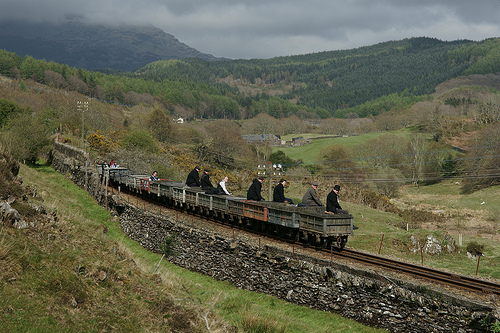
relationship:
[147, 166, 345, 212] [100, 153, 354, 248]
people on train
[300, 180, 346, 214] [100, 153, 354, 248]
men riding train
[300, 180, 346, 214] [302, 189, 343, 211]
men wearing coats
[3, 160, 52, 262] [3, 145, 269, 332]
rocks on hillside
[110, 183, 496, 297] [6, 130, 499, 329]
tracks in field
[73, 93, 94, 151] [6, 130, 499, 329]
lights in field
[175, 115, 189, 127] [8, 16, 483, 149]
house in background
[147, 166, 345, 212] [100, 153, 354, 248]
people on top of train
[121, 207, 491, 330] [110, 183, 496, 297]
wall under tracks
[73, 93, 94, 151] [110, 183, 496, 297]
lights by tracks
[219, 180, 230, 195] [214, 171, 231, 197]
sleeve on passenger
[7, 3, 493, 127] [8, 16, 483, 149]
mountains in background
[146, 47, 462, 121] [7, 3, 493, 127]
trees on mountains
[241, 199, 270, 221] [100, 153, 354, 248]
cart on train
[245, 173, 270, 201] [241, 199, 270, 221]
person sitting on cart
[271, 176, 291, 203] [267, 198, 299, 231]
person sitting on cart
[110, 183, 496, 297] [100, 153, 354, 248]
tracks below train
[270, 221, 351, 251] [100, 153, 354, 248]
wheels on train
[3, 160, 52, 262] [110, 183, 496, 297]
rocks next to tracks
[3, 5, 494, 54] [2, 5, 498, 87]
clouds in sky